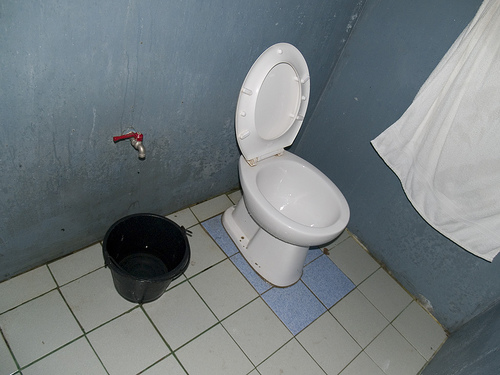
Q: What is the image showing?
A: It is showing a bathroom.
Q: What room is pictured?
A: It is a bathroom.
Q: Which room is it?
A: It is a bathroom.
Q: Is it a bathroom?
A: Yes, it is a bathroom.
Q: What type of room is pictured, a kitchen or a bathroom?
A: It is a bathroom.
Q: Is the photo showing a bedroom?
A: No, the picture is showing a bathroom.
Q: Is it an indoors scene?
A: Yes, it is indoors.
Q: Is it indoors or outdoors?
A: It is indoors.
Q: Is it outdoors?
A: No, it is indoors.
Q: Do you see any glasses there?
A: No, there are no glasses.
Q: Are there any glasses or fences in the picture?
A: No, there are no glasses or fences.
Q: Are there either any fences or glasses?
A: No, there are no glasses or fences.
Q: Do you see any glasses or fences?
A: No, there are no glasses or fences.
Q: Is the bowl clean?
A: Yes, the bowl is clean.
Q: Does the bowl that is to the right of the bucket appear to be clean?
A: Yes, the bowl is clean.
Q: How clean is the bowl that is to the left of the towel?
A: The bowl is clean.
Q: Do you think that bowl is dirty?
A: No, the bowl is clean.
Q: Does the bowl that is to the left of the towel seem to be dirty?
A: No, the bowl is clean.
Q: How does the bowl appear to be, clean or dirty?
A: The bowl is clean.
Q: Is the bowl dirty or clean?
A: The bowl is clean.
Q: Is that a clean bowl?
A: Yes, that is a clean bowl.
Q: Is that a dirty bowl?
A: No, that is a clean bowl.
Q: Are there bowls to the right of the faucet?
A: Yes, there is a bowl to the right of the faucet.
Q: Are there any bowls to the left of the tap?
A: No, the bowl is to the right of the tap.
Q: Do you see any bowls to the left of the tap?
A: No, the bowl is to the right of the tap.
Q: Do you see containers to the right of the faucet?
A: No, there is a bowl to the right of the faucet.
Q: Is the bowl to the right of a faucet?
A: Yes, the bowl is to the right of a faucet.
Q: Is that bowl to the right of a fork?
A: No, the bowl is to the right of a faucet.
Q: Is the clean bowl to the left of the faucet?
A: No, the bowl is to the right of the faucet.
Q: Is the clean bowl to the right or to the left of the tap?
A: The bowl is to the right of the tap.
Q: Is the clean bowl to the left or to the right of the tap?
A: The bowl is to the right of the tap.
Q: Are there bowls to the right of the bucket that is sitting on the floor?
A: Yes, there is a bowl to the right of the bucket.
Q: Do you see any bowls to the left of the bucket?
A: No, the bowl is to the right of the bucket.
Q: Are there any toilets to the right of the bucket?
A: No, there is a bowl to the right of the bucket.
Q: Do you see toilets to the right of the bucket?
A: No, there is a bowl to the right of the bucket.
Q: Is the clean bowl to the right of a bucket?
A: Yes, the bowl is to the right of a bucket.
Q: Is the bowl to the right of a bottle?
A: No, the bowl is to the right of a bucket.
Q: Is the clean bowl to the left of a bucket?
A: No, the bowl is to the right of a bucket.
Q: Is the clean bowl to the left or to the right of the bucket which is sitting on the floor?
A: The bowl is to the right of the bucket.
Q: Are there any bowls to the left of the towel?
A: Yes, there is a bowl to the left of the towel.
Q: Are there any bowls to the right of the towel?
A: No, the bowl is to the left of the towel.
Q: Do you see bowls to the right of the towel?
A: No, the bowl is to the left of the towel.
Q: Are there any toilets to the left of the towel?
A: No, there is a bowl to the left of the towel.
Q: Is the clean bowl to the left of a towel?
A: Yes, the bowl is to the left of a towel.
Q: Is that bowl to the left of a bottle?
A: No, the bowl is to the left of a towel.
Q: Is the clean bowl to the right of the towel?
A: No, the bowl is to the left of the towel.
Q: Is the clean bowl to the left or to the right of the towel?
A: The bowl is to the left of the towel.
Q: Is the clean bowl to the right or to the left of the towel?
A: The bowl is to the left of the towel.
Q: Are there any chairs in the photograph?
A: No, there are no chairs.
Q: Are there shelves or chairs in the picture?
A: No, there are no chairs or shelves.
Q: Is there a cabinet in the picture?
A: No, there are no cabinets.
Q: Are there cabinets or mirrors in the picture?
A: No, there are no cabinets or mirrors.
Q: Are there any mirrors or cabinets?
A: No, there are no cabinets or mirrors.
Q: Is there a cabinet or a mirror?
A: No, there are no cabinets or mirrors.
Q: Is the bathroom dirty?
A: Yes, the bathroom is dirty.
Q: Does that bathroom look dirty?
A: Yes, the bathroom is dirty.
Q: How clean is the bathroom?
A: The bathroom is dirty.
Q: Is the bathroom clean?
A: No, the bathroom is dirty.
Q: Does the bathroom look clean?
A: No, the bathroom is dirty.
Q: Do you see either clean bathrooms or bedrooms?
A: No, there is a bathroom but it is dirty.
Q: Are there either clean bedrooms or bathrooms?
A: No, there is a bathroom but it is dirty.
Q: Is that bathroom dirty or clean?
A: The bathroom is dirty.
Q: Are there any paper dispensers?
A: No, there are no paper dispensers.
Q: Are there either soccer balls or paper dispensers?
A: No, there are no paper dispensers or soccer balls.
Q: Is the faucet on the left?
A: Yes, the faucet is on the left of the image.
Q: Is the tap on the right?
A: No, the tap is on the left of the image.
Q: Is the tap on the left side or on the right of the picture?
A: The tap is on the left of the image.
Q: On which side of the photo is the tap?
A: The tap is on the left of the image.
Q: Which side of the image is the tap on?
A: The tap is on the left of the image.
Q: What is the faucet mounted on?
A: The faucet is mounted on the wall.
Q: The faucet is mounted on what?
A: The faucet is mounted on the wall.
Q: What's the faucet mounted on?
A: The faucet is mounted on the wall.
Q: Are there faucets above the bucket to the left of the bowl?
A: Yes, there is a faucet above the bucket.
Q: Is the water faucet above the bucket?
A: Yes, the faucet is above the bucket.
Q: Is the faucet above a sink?
A: No, the faucet is above the bucket.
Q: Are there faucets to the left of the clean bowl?
A: Yes, there is a faucet to the left of the bowl.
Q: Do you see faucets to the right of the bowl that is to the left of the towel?
A: No, the faucet is to the left of the bowl.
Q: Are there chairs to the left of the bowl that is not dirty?
A: No, there is a faucet to the left of the bowl.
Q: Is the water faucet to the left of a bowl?
A: Yes, the faucet is to the left of a bowl.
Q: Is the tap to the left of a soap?
A: No, the tap is to the left of a bowl.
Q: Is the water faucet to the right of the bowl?
A: No, the tap is to the left of the bowl.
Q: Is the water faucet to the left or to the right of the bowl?
A: The tap is to the left of the bowl.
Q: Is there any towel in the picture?
A: Yes, there is a towel.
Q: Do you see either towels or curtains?
A: Yes, there is a towel.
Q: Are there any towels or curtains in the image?
A: Yes, there is a towel.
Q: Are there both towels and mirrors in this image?
A: No, there is a towel but no mirrors.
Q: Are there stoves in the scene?
A: No, there are no stoves.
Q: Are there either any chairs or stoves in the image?
A: No, there are no stoves or chairs.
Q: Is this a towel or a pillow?
A: This is a towel.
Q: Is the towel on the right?
A: Yes, the towel is on the right of the image.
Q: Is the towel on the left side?
A: No, the towel is on the right of the image.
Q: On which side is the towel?
A: The towel is on the right of the image.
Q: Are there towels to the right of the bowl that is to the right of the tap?
A: Yes, there is a towel to the right of the bowl.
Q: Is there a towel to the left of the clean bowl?
A: No, the towel is to the right of the bowl.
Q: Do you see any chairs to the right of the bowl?
A: No, there is a towel to the right of the bowl.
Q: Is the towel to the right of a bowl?
A: Yes, the towel is to the right of a bowl.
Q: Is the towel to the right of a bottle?
A: No, the towel is to the right of a bowl.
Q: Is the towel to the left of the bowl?
A: No, the towel is to the right of the bowl.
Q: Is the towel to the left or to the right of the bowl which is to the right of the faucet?
A: The towel is to the right of the bowl.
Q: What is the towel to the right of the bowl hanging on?
A: The towel is hanging on the wall.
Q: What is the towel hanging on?
A: The towel is hanging on the wall.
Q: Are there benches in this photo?
A: No, there are no benches.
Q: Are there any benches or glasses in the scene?
A: No, there are no benches or glasses.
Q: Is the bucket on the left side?
A: Yes, the bucket is on the left of the image.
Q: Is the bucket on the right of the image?
A: No, the bucket is on the left of the image.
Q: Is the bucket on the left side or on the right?
A: The bucket is on the left of the image.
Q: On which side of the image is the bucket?
A: The bucket is on the left of the image.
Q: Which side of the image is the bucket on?
A: The bucket is on the left of the image.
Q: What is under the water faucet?
A: The bucket is under the faucet.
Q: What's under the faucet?
A: The bucket is under the faucet.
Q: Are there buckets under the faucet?
A: Yes, there is a bucket under the faucet.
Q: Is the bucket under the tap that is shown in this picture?
A: Yes, the bucket is under the tap.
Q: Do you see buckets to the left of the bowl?
A: Yes, there is a bucket to the left of the bowl.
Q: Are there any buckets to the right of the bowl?
A: No, the bucket is to the left of the bowl.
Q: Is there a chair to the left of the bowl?
A: No, there is a bucket to the left of the bowl.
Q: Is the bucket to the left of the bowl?
A: Yes, the bucket is to the left of the bowl.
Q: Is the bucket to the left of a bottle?
A: No, the bucket is to the left of the bowl.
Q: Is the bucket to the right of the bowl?
A: No, the bucket is to the left of the bowl.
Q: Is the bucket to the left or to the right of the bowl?
A: The bucket is to the left of the bowl.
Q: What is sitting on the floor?
A: The bucket is sitting on the floor.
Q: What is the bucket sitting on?
A: The bucket is sitting on the floor.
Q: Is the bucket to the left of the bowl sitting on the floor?
A: Yes, the bucket is sitting on the floor.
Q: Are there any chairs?
A: No, there are no chairs.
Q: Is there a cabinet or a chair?
A: No, there are no chairs or cabinets.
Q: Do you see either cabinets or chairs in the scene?
A: No, there are no chairs or cabinets.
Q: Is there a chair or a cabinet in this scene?
A: No, there are no chairs or cabinets.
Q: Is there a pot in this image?
A: No, there are no pots.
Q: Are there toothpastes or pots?
A: No, there are no pots or toothpastes.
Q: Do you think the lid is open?
A: Yes, the lid is open.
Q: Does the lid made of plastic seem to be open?
A: Yes, the lid is open.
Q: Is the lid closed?
A: No, the lid is open.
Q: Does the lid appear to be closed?
A: No, the lid is open.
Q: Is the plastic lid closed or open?
A: The lid is open.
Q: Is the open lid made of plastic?
A: Yes, the lid is made of plastic.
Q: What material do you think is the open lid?
A: The lid is made of plastic.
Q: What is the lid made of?
A: The lid is made of plastic.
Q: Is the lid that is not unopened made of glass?
A: No, the lid is made of plastic.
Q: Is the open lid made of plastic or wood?
A: The lid is made of plastic.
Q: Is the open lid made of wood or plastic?
A: The lid is made of plastic.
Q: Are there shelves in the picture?
A: No, there are no shelves.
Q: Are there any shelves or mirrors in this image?
A: No, there are no shelves or mirrors.